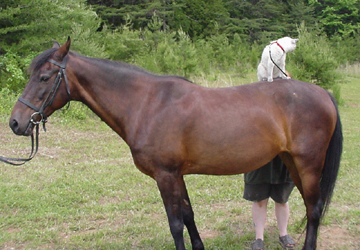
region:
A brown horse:
[8, 23, 359, 212]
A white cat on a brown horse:
[18, 20, 329, 139]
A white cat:
[252, 28, 302, 89]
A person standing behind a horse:
[226, 76, 339, 247]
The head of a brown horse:
[9, 15, 92, 148]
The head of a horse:
[15, 28, 97, 172]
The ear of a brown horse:
[47, 34, 83, 60]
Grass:
[54, 171, 117, 237]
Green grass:
[12, 190, 120, 248]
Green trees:
[120, 2, 268, 52]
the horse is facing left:
[15, 44, 341, 249]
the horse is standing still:
[13, 43, 341, 249]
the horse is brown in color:
[13, 37, 340, 247]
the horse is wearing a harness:
[14, 42, 77, 129]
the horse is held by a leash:
[1, 119, 44, 167]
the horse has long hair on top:
[29, 49, 59, 69]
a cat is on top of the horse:
[254, 35, 299, 83]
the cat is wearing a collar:
[273, 40, 286, 53]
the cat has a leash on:
[268, 44, 289, 77]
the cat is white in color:
[257, 36, 296, 81]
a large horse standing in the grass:
[11, 14, 340, 245]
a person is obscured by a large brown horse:
[8, 5, 337, 242]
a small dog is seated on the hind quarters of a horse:
[255, 21, 296, 95]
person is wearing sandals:
[242, 232, 296, 244]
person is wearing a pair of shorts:
[238, 162, 302, 198]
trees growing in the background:
[15, 0, 304, 33]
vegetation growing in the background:
[9, 1, 250, 42]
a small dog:
[255, 26, 306, 103]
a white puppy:
[243, 28, 311, 97]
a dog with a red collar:
[257, 20, 300, 92]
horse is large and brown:
[15, 45, 337, 246]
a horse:
[14, 27, 357, 246]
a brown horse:
[11, 33, 358, 247]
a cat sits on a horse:
[12, 19, 358, 248]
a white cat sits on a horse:
[25, 14, 358, 245]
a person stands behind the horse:
[208, 39, 358, 248]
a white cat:
[243, 27, 329, 104]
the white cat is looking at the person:
[244, 25, 338, 121]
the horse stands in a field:
[21, 25, 338, 248]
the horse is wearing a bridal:
[12, 27, 347, 245]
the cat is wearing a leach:
[249, 33, 311, 92]